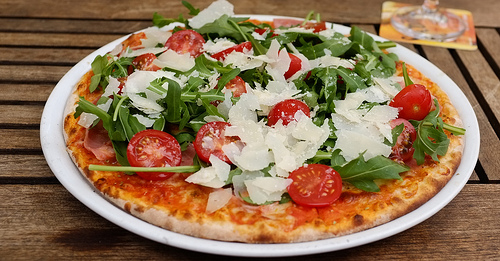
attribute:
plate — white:
[39, 13, 481, 256]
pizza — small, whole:
[62, 1, 466, 245]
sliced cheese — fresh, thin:
[79, 0, 404, 214]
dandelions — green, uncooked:
[73, 1, 466, 194]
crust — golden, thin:
[62, 18, 466, 245]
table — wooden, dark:
[1, 1, 500, 261]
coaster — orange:
[378, 1, 478, 54]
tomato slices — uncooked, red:
[119, 22, 432, 208]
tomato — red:
[287, 164, 344, 208]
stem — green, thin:
[88, 162, 200, 173]